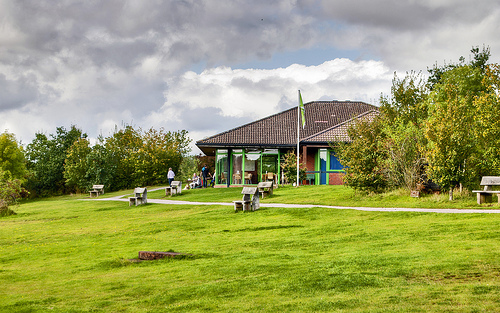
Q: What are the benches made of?
A: Wood.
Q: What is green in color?
A: Grass.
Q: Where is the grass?
A: On the ground.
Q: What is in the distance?
A: A building.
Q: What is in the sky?
A: Clouds.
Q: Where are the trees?
A: On the ground.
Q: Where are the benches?
A: In the distance.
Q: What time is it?
A: Afternoon.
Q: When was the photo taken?
A: During the daytime.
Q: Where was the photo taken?
A: Outside somewhere.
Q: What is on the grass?
A: Benches.